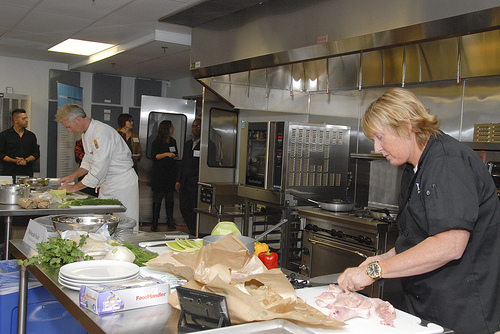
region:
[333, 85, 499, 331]
A woman cutting meat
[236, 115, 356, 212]
A large grey cooking oven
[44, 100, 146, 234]
A chef in all white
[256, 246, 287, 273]
A red pepper laying on the table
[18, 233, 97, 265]
A stack of green lettuce on the table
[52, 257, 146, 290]
A stack of four white plates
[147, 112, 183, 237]
A woman standing wearing all black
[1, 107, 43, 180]
A man standing wearing all black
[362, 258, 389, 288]
A gold and black wrist watch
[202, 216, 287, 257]
A mixing bowl laying on the table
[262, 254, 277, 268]
the pepper is red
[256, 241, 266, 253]
the pepper is orange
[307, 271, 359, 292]
she is cutting with the knife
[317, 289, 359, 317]
the chicken is raw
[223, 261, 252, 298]
the paper is brown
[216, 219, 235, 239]
the cabbage is green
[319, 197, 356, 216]
the pan is on the stove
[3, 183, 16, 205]
the pot is silver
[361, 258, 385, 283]
she is wearing a watch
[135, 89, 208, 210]
the doors are open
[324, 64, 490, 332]
Woman is in the foreground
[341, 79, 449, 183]
Woman has blonde colored hair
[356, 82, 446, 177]
A side view of a woman's head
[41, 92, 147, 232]
An older man in the background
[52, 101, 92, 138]
Man has gray colored hair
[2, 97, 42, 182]
Man is wearing a black shirt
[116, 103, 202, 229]
Three people next to each other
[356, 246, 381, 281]
Woman is wearing a wristwatch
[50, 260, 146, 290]
white plates on the table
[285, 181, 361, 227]
A silver frying pan in the background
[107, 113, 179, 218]
person standing against wall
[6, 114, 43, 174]
person standing against wall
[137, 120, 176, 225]
person standing against wall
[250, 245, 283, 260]
bell pepper on counter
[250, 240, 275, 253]
bell pepper on counter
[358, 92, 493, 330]
woman preparing food in kitche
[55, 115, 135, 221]
chef cooking food in kitchen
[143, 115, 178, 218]
wait staff waiting for instruction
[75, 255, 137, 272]
stack of plate on table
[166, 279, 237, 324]
ipod on the table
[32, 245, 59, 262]
some green leaves on the table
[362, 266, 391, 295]
a man wearing a watch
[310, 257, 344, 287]
a man with a knife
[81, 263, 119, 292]
white plates on the table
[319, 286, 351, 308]
meat on the cutting board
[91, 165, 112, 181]
a man in white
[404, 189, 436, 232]
a man in black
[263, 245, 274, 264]
a red pepper on table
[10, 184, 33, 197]
a pot on table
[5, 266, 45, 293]
a blue trash can on ground